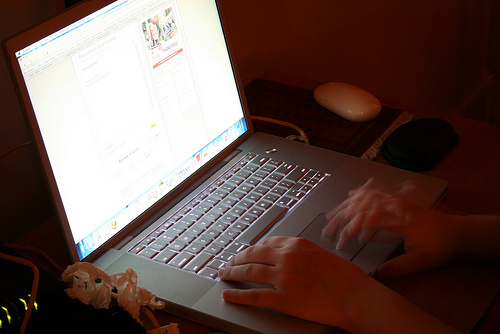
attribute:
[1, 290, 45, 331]
lights — green, power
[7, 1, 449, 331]
laptop — silver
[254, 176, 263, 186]
key — silver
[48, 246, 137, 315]
tissue — white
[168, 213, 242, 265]
keyboard — grey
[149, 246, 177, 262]
keys — black, white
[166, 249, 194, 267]
keys — black, white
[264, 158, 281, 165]
keys — black, white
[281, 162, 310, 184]
keys — black, white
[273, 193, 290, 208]
keys — black, white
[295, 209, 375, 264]
mouse — electronic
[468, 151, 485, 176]
desk — brown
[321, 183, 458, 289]
hand — blurry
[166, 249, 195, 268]
key — black, white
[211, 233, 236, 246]
key — black, white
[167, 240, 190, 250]
key — black, white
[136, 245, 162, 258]
key — white, black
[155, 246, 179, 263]
key — white, black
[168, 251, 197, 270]
key — white, black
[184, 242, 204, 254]
key — white, black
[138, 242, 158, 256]
key — white, black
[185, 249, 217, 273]
key — white, black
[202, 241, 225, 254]
key — white, black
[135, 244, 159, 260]
key — black, white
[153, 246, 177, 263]
key — black, white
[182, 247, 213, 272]
key — black, white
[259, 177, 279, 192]
key — black, white